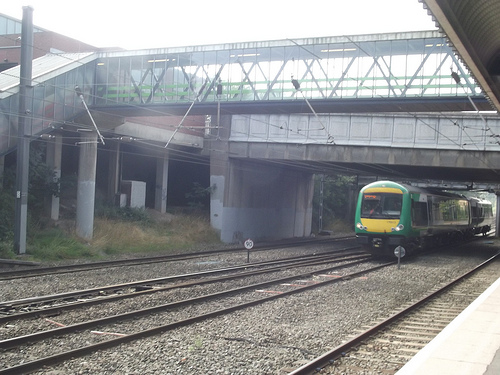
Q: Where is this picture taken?
A: A railway.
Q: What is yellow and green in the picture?
A: A train.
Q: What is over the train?
A: A bridge.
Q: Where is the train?
A: On the tracks.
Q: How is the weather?
A: Sunny.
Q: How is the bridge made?
A: Of steel and glass.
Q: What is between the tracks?
A: Gravel.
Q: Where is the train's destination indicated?
A: The train"s front.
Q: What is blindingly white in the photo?
A: The sky.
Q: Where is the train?
A: On the tracks.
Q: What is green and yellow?
A: The train.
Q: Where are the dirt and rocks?
A: The tracks.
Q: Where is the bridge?
A: Over the tracks.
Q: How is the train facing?
A: Forward.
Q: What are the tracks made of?
A: Metal.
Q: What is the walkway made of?
A: Glass windows.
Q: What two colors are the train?
A: Yellow, green.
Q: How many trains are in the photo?
A: One.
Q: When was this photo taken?
A: Daytime.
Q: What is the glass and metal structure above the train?
A: Walkway.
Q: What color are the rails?
A: Silver.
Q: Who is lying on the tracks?
A: No one.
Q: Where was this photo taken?
A: Train Station.